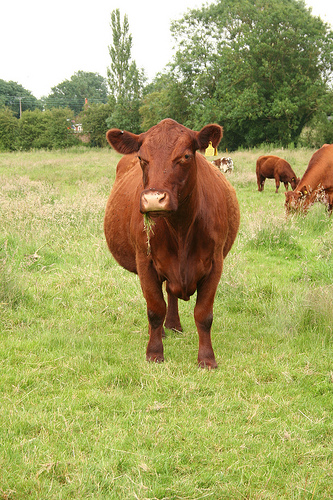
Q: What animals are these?
A: Cows.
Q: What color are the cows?
A: Brown.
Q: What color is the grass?
A: Green.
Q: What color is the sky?
A: White.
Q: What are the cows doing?
A: Eating.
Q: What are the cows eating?
A: Grass.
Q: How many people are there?
A: None.